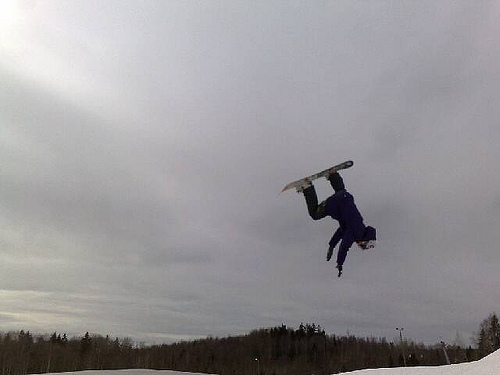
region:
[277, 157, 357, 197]
Person on a board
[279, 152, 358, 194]
Person is on a board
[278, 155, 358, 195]
Person on a snowboard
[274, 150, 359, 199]
Person is on a snowboard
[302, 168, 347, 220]
Person wearing pants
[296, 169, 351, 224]
Person is wearing pants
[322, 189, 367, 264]
Person wearing a jacket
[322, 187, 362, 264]
Person is wearing a jacket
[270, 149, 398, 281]
Person in the air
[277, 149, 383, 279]
Person is in the air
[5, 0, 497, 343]
snowboarder upside down during jump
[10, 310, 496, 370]
trees covering hills in distance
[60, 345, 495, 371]
top of snow surface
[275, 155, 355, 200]
feet under top of snowboard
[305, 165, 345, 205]
square formed by legs and snowboard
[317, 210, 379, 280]
arms raised in front of body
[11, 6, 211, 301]
muted rays of light across the sky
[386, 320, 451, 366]
tall and short pole in the distance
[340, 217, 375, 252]
head tilted toward back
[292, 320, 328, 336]
outline of tallest trees on hill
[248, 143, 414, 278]
Person in the air.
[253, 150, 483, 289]
Person who is snowboarding.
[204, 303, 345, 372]
Trees in the background.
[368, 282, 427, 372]
Light pole on the mountain.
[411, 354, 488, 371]
Snow on the mountain.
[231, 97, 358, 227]
Snowboard in the air.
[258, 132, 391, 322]
Person with their arms out.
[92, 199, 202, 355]
Clouds in the sky.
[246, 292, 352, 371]
Green trees in the background.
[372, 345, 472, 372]
White snow on the mountain.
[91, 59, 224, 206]
the sky is overcast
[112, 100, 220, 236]
the sky is overcast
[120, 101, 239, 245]
the sky is overcast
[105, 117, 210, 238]
the sky is overcast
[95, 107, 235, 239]
the sky is overcast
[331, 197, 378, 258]
the jacket is blue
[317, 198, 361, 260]
the jacket is blue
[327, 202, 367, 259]
the jacket is blue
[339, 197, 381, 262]
the jacket is blue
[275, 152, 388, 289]
A snowboarder in mid air after a trick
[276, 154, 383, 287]
A snowboarder in mid air after a trick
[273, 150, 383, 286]
A snowboarder in mid air after a trick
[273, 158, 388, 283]
A snowboarder in mid air after a trick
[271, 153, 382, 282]
A snowboarder in mid air after a trick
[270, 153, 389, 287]
A snowboarder in mid air after a trick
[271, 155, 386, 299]
A snowboarder in mid air after a trick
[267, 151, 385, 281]
A snowboarder in mid air after a trick